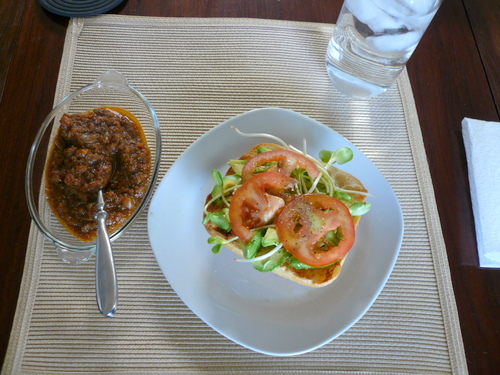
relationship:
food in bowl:
[40, 105, 157, 239] [20, 62, 170, 272]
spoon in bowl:
[92, 189, 119, 316] [21, 61, 159, 264]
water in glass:
[327, 1, 437, 105] [322, 1, 442, 101]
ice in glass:
[369, 33, 421, 50] [320, 3, 437, 97]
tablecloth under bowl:
[0, 11, 467, 374] [21, 61, 159, 264]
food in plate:
[203, 125, 370, 287] [145, 106, 405, 357]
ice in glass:
[366, 31, 423, 53] [306, 20, 437, 98]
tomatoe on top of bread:
[276, 194, 355, 268] [202, 141, 368, 288]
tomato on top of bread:
[229, 173, 295, 243] [202, 141, 368, 288]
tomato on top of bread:
[239, 147, 318, 183] [202, 141, 368, 288]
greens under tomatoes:
[201, 124, 372, 272] [278, 193, 355, 270]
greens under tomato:
[201, 124, 372, 272] [227, 171, 300, 243]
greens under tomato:
[201, 124, 372, 272] [240, 148, 320, 185]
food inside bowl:
[41, 105, 153, 244] [21, 61, 159, 264]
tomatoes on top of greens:
[278, 193, 355, 270] [201, 124, 372, 272]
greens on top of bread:
[201, 124, 372, 272] [202, 141, 368, 288]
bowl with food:
[171, 105, 444, 357] [179, 137, 466, 327]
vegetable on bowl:
[213, 137, 377, 264] [144, 106, 407, 360]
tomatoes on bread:
[239, 161, 348, 263] [202, 141, 368, 288]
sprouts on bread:
[299, 148, 341, 198] [202, 141, 368, 288]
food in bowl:
[41, 105, 153, 244] [22, 69, 166, 260]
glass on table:
[319, 2, 451, 122] [5, 2, 480, 369]